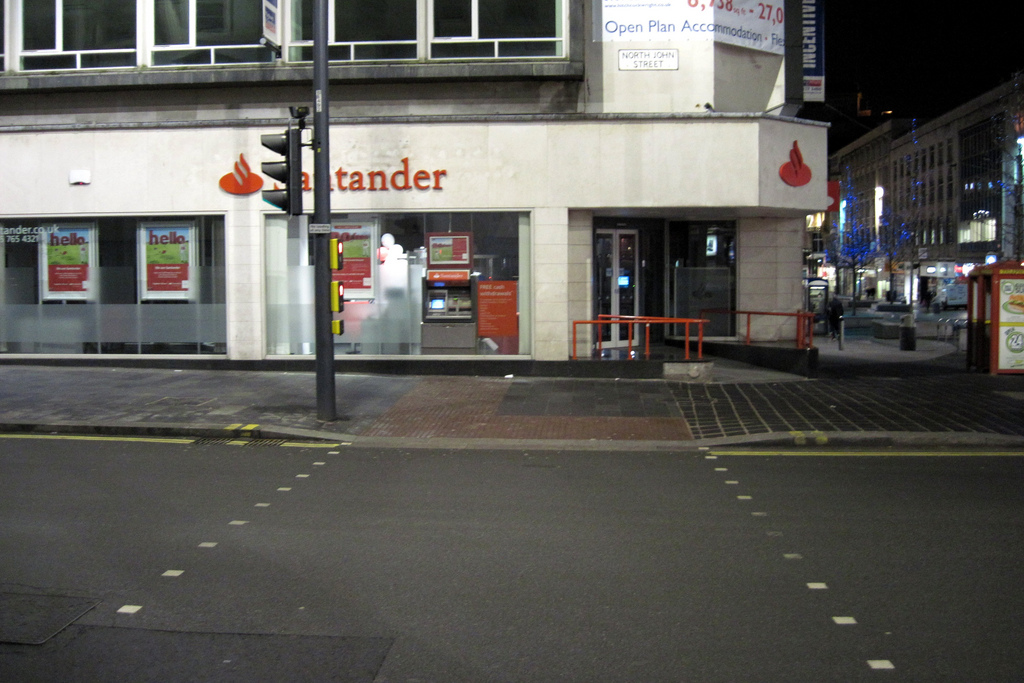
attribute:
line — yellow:
[1, 427, 337, 449]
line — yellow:
[703, 440, 1023, 464]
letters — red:
[270, 159, 452, 196]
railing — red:
[569, 309, 712, 364]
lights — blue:
[812, 175, 912, 275]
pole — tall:
[300, 22, 342, 386]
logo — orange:
[231, 163, 452, 196]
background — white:
[170, 100, 659, 280]